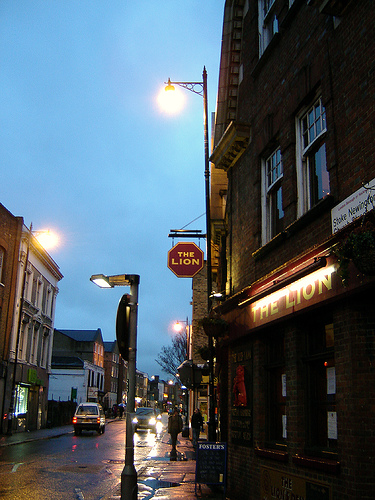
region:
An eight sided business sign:
[167, 240, 201, 277]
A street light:
[87, 270, 135, 495]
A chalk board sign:
[192, 441, 230, 497]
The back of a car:
[70, 401, 105, 435]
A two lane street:
[1, 407, 193, 499]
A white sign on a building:
[327, 176, 372, 234]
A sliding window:
[292, 85, 332, 218]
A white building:
[48, 353, 104, 406]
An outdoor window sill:
[293, 444, 338, 470]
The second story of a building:
[169, 2, 372, 303]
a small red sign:
[152, 238, 215, 294]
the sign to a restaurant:
[239, 255, 335, 338]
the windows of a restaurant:
[263, 357, 362, 434]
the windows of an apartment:
[254, 139, 352, 211]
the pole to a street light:
[115, 289, 148, 472]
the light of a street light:
[89, 267, 134, 297]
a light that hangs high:
[144, 73, 218, 121]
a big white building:
[60, 331, 108, 414]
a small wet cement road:
[31, 450, 96, 498]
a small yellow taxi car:
[72, 400, 105, 438]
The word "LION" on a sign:
[282, 269, 334, 311]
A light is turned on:
[148, 69, 191, 126]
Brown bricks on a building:
[219, 0, 373, 498]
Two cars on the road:
[0, 400, 169, 498]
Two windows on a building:
[254, 84, 334, 246]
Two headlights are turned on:
[126, 412, 161, 430]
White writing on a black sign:
[193, 439, 228, 456]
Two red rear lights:
[69, 411, 105, 429]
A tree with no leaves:
[153, 325, 190, 386]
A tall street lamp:
[4, 216, 61, 441]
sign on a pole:
[163, 225, 218, 281]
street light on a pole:
[153, 71, 211, 112]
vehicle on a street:
[70, 398, 108, 439]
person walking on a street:
[166, 406, 186, 457]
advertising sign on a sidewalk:
[190, 439, 230, 499]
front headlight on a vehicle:
[147, 417, 157, 426]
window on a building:
[291, 87, 337, 222]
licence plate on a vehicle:
[80, 415, 92, 425]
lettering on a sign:
[196, 441, 227, 452]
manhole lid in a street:
[103, 457, 128, 466]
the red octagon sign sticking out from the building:
[167, 241, 203, 276]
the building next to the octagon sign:
[167, 0, 373, 499]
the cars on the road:
[72, 401, 160, 431]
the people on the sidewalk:
[105, 402, 203, 453]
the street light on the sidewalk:
[90, 274, 138, 499]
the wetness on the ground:
[0, 410, 227, 498]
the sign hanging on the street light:
[115, 292, 128, 360]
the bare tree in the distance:
[154, 326, 186, 387]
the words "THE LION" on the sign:
[251, 273, 330, 320]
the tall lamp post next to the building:
[157, 66, 218, 489]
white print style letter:
[249, 301, 257, 322]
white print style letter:
[261, 301, 270, 321]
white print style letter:
[268, 294, 278, 316]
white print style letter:
[283, 287, 298, 308]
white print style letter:
[293, 286, 303, 303]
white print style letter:
[301, 280, 316, 299]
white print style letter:
[315, 268, 332, 295]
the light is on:
[160, 87, 181, 112]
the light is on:
[36, 229, 54, 245]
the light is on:
[95, 276, 113, 284]